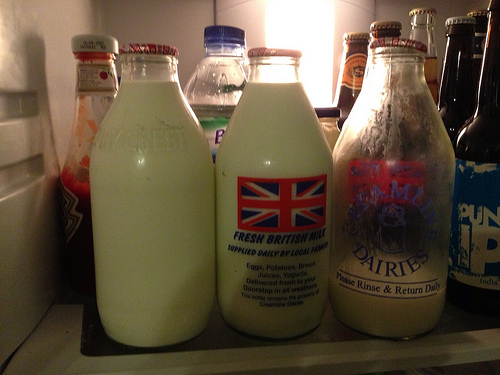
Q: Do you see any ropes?
A: No, there are no ropes.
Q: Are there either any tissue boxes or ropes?
A: No, there are no ropes or tissue boxes.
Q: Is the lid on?
A: Yes, the lid is on.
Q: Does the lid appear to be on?
A: Yes, the lid is on.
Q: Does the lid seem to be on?
A: Yes, the lid is on.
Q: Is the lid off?
A: No, the lid is on.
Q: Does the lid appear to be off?
A: No, the lid is on.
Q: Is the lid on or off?
A: The lid is on.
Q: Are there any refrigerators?
A: Yes, there is a refrigerator.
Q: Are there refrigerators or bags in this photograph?
A: Yes, there is a refrigerator.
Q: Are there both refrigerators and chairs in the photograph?
A: No, there is a refrigerator but no chairs.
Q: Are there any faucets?
A: No, there are no faucets.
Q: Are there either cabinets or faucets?
A: No, there are no faucets or cabinets.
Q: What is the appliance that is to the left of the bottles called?
A: The appliance is a refrigerator.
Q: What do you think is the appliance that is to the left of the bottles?
A: The appliance is a refrigerator.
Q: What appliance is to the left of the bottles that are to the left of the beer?
A: The appliance is a refrigerator.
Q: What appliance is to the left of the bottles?
A: The appliance is a refrigerator.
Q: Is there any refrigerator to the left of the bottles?
A: Yes, there is a refrigerator to the left of the bottles.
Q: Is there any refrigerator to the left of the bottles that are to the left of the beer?
A: Yes, there is a refrigerator to the left of the bottles.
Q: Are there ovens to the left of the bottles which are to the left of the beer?
A: No, there is a refrigerator to the left of the bottles.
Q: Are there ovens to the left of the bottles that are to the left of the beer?
A: No, there is a refrigerator to the left of the bottles.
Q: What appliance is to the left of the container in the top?
A: The appliance is a refrigerator.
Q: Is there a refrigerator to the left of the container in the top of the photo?
A: Yes, there is a refrigerator to the left of the container.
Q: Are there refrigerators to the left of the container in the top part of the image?
A: Yes, there is a refrigerator to the left of the container.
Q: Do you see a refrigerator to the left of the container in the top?
A: Yes, there is a refrigerator to the left of the container.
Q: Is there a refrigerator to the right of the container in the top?
A: No, the refrigerator is to the left of the container.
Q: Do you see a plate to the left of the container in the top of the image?
A: No, there is a refrigerator to the left of the container.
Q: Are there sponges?
A: No, there are no sponges.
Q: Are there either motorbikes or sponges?
A: No, there are no sponges or motorbikes.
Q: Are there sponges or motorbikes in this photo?
A: No, there are no sponges or motorbikes.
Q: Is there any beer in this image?
A: Yes, there is beer.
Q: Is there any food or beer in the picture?
A: Yes, there is beer.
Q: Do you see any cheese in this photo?
A: No, there is no cheese.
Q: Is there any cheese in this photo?
A: No, there is no cheese.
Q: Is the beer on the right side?
A: Yes, the beer is on the right of the image.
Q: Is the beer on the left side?
A: No, the beer is on the right of the image.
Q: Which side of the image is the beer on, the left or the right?
A: The beer is on the right of the image.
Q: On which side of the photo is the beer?
A: The beer is on the right of the image.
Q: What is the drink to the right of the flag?
A: The drink is beer.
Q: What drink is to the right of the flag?
A: The drink is beer.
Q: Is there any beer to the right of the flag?
A: Yes, there is beer to the right of the flag.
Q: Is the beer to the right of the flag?
A: Yes, the beer is to the right of the flag.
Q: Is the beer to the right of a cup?
A: No, the beer is to the right of the flag.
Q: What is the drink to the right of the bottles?
A: The drink is beer.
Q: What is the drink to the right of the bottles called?
A: The drink is beer.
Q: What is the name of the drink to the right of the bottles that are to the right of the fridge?
A: The drink is beer.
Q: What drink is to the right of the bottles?
A: The drink is beer.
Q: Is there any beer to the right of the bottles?
A: Yes, there is beer to the right of the bottles.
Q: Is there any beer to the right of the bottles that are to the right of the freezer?
A: Yes, there is beer to the right of the bottles.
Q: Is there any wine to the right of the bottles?
A: No, there is beer to the right of the bottles.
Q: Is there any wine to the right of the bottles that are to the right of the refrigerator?
A: No, there is beer to the right of the bottles.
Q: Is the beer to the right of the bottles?
A: Yes, the beer is to the right of the bottles.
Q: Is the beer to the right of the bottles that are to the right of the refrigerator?
A: Yes, the beer is to the right of the bottles.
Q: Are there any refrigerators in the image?
A: Yes, there is a refrigerator.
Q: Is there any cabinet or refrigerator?
A: Yes, there is a refrigerator.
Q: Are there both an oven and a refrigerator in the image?
A: No, there is a refrigerator but no ovens.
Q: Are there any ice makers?
A: No, there are no ice makers.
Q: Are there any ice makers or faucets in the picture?
A: No, there are no ice makers or faucets.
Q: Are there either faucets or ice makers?
A: No, there are no ice makers or faucets.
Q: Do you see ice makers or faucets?
A: No, there are no ice makers or faucets.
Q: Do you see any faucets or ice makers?
A: No, there are no ice makers or faucets.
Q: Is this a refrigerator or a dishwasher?
A: This is a refrigerator.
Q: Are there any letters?
A: Yes, there are letters.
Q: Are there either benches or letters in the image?
A: Yes, there are letters.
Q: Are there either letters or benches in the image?
A: Yes, there are letters.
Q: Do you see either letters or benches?
A: Yes, there are letters.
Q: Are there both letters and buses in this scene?
A: No, there are letters but no buses.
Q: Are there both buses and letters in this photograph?
A: No, there are letters but no buses.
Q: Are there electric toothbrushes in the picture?
A: No, there are no electric toothbrushes.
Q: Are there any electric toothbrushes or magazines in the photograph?
A: No, there are no electric toothbrushes or magazines.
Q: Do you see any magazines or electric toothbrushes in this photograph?
A: No, there are no electric toothbrushes or magazines.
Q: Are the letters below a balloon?
A: No, the letters are below the flag.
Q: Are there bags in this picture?
A: No, there are no bags.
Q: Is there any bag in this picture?
A: No, there are no bags.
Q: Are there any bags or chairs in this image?
A: No, there are no bags or chairs.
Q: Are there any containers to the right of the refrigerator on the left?
A: Yes, there is a container to the right of the refrigerator.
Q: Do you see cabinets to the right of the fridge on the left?
A: No, there is a container to the right of the refrigerator.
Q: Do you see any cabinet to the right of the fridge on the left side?
A: No, there is a container to the right of the refrigerator.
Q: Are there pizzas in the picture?
A: No, there are no pizzas.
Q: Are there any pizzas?
A: No, there are no pizzas.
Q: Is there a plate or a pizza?
A: No, there are no pizzas or plates.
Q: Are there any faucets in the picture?
A: No, there are no faucets.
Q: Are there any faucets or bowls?
A: No, there are no faucets or bowls.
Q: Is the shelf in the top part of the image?
A: No, the shelf is in the bottom of the image.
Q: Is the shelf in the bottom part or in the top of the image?
A: The shelf is in the bottom of the image.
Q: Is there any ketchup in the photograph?
A: Yes, there is ketchup.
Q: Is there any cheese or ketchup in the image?
A: Yes, there is ketchup.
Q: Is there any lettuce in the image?
A: No, there is no lettuce.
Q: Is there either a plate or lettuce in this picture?
A: No, there are no lettuce or plates.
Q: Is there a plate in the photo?
A: No, there are no plates.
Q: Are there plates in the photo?
A: No, there are no plates.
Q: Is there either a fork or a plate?
A: No, there are no plates or forks.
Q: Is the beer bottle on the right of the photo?
A: Yes, the beer bottle is on the right of the image.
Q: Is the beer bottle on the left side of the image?
A: No, the beer bottle is on the right of the image.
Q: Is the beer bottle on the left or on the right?
A: The beer bottle is on the right of the image.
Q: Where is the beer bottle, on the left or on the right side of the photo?
A: The beer bottle is on the right of the image.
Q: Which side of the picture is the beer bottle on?
A: The beer bottle is on the right of the image.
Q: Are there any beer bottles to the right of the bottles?
A: Yes, there is a beer bottle to the right of the bottles.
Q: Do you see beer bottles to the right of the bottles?
A: Yes, there is a beer bottle to the right of the bottles.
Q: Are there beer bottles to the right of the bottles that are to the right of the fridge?
A: Yes, there is a beer bottle to the right of the bottles.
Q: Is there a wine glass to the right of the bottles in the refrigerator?
A: No, there is a beer bottle to the right of the bottles.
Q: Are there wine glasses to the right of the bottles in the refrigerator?
A: No, there is a beer bottle to the right of the bottles.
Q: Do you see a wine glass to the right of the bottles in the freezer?
A: No, there is a beer bottle to the right of the bottles.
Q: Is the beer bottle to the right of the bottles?
A: Yes, the beer bottle is to the right of the bottles.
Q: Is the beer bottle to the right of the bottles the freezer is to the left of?
A: Yes, the beer bottle is to the right of the bottles.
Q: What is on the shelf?
A: The beer bottle is on the shelf.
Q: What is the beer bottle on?
A: The beer bottle is on the shelf.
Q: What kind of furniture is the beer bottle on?
A: The beer bottle is on the shelf.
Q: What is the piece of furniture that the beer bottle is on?
A: The piece of furniture is a shelf.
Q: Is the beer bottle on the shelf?
A: Yes, the beer bottle is on the shelf.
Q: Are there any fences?
A: No, there are no fences.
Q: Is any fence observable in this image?
A: No, there are no fences.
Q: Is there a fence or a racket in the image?
A: No, there are no fences or rackets.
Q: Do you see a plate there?
A: No, there are no plates.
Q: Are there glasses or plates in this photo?
A: No, there are no plates or glasses.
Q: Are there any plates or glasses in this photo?
A: No, there are no plates or glasses.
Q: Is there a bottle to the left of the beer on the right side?
A: Yes, there are bottles to the left of the beer.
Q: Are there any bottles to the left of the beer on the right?
A: Yes, there are bottles to the left of the beer.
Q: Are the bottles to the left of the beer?
A: Yes, the bottles are to the left of the beer.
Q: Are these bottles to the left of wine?
A: No, the bottles are to the left of the beer.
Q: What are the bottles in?
A: The bottles are in the fridge.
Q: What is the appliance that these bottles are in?
A: The appliance is a refrigerator.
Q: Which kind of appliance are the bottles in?
A: The bottles are in the freezer.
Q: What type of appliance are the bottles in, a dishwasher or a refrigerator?
A: The bottles are in a refrigerator.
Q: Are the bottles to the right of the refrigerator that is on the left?
A: Yes, the bottles are to the right of the fridge.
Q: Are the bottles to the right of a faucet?
A: No, the bottles are to the right of the fridge.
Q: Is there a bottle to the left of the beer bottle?
A: Yes, there are bottles to the left of the beer bottle.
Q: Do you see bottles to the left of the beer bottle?
A: Yes, there are bottles to the left of the beer bottle.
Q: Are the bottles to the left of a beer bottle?
A: Yes, the bottles are to the left of a beer bottle.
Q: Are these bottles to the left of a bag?
A: No, the bottles are to the left of a beer bottle.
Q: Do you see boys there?
A: No, there are no boys.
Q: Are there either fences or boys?
A: No, there are no boys or fences.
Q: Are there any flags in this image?
A: Yes, there is a flag.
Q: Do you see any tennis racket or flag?
A: Yes, there is a flag.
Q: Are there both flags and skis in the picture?
A: No, there is a flag but no skis.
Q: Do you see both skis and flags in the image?
A: No, there is a flag but no skis.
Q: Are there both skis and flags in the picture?
A: No, there is a flag but no skis.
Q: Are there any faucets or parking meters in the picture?
A: No, there are no faucets or parking meters.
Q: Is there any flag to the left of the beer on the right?
A: Yes, there is a flag to the left of the beer.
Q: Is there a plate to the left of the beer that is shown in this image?
A: No, there is a flag to the left of the beer.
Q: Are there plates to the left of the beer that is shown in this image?
A: No, there is a flag to the left of the beer.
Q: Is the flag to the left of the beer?
A: Yes, the flag is to the left of the beer.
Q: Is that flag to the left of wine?
A: No, the flag is to the left of the beer.